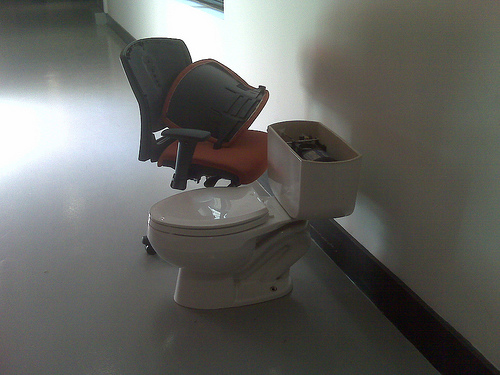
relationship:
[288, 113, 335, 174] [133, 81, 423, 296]
parts inside of toilet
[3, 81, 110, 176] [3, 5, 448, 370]
reflection on floor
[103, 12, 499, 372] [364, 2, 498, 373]
trim at wall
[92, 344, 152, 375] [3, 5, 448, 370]
part of a floor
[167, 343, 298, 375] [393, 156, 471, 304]
part of a shape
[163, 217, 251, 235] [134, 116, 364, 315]
edge of a toilet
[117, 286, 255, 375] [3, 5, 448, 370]
part of a floor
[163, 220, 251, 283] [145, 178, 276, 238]
edge of a lid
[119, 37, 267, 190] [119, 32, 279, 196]
chair a chair